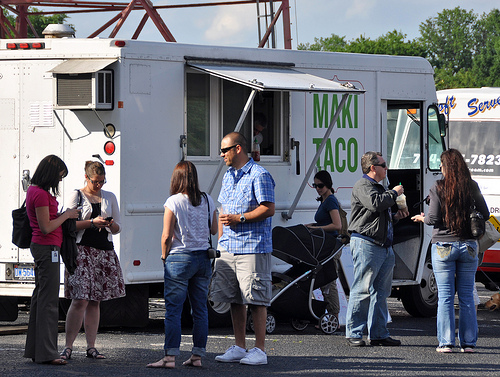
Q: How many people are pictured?
A: 9.